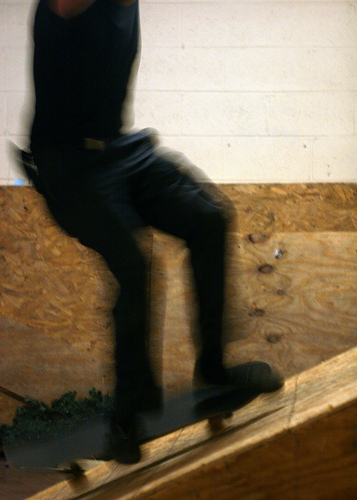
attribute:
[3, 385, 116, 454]
grass — green 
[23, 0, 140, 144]
shirt — black, short sleeved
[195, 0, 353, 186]
wall — white, painted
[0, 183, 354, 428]
wall — wood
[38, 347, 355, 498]
ramp — wooden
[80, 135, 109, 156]
buckle — black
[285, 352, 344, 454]
sloppy area — sloped 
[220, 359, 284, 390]
shoe — black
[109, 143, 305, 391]
sneakers — black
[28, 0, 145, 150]
shirt — dark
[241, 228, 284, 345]
knots — brown 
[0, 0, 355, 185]
wall — white, painted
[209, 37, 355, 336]
wall — wooden 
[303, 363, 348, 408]
ramp — wood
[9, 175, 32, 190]
sticker — blue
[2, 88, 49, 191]
wall — white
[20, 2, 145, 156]
shirt — black 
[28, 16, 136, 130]
tshirt — black 